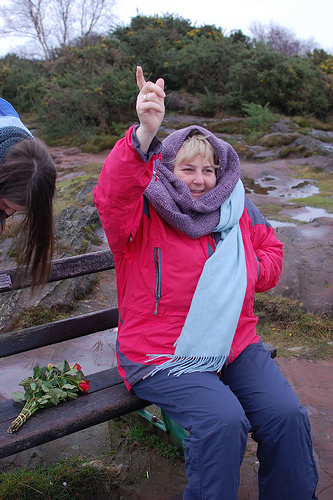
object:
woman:
[92, 61, 319, 499]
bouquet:
[5, 356, 91, 436]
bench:
[0, 245, 278, 468]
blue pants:
[132, 338, 320, 500]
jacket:
[92, 123, 284, 392]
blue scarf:
[140, 174, 247, 381]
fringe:
[140, 351, 227, 379]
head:
[162, 128, 224, 211]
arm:
[92, 124, 164, 251]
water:
[237, 174, 317, 205]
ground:
[0, 137, 332, 499]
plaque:
[0, 272, 13, 287]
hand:
[134, 63, 168, 134]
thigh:
[146, 359, 247, 444]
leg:
[228, 341, 319, 499]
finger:
[134, 63, 147, 92]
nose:
[193, 168, 207, 186]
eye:
[180, 166, 196, 175]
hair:
[161, 134, 222, 172]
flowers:
[76, 378, 91, 396]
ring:
[142, 91, 149, 103]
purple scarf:
[140, 122, 239, 237]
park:
[0, 114, 332, 499]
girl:
[0, 99, 57, 234]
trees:
[0, 7, 332, 126]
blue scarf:
[0, 114, 36, 150]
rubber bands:
[22, 403, 32, 418]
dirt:
[0, 145, 332, 499]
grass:
[252, 287, 333, 360]